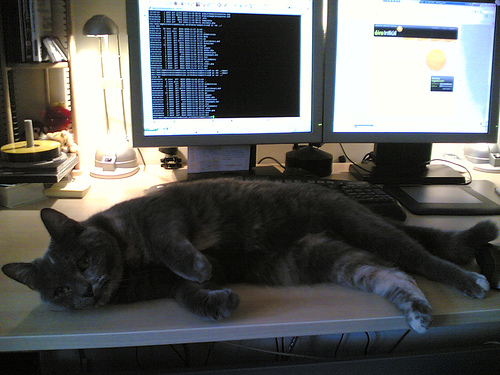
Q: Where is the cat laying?
A: Table.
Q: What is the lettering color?
A: White.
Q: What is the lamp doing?
A: On.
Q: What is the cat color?
A: Grey.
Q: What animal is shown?
A: A cat.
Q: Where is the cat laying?
A: A desk.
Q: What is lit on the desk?
A: Computers.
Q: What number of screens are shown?
A: Two.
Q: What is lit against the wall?
A: A lamp.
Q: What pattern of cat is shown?
A: A tabby.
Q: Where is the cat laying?
A: A desk.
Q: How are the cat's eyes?
A: Open.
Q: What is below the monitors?
A: A cat.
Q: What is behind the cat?
A: Monitors.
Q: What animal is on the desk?
A: A cat.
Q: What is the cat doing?
A: Resting.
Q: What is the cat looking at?
A: The camera.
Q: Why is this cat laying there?
A: He Is relaxing.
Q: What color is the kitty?
A: Gray and white.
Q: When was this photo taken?
A: Night.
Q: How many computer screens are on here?
A: 2.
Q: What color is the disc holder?
A: White.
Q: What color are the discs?
A: Yellow.